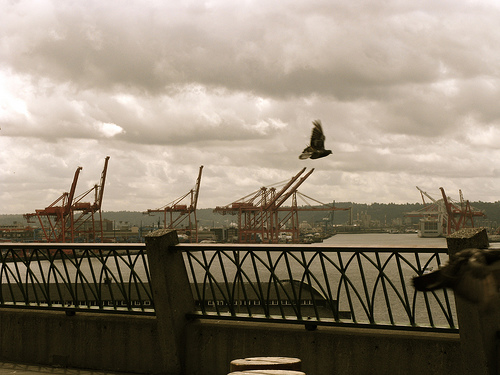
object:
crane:
[23, 155, 112, 257]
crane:
[142, 165, 205, 243]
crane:
[213, 167, 350, 245]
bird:
[297, 116, 333, 159]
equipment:
[21, 156, 116, 256]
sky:
[0, 0, 498, 204]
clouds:
[1, 0, 499, 203]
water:
[0, 226, 500, 342]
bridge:
[0, 227, 499, 375]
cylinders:
[228, 355, 302, 373]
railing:
[0, 227, 500, 375]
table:
[227, 354, 304, 375]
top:
[230, 355, 300, 366]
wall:
[0, 305, 499, 373]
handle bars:
[0, 229, 500, 253]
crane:
[401, 186, 486, 236]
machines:
[19, 156, 486, 250]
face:
[408, 249, 478, 293]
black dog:
[410, 228, 500, 375]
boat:
[417, 215, 443, 238]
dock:
[2, 279, 351, 321]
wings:
[310, 118, 327, 149]